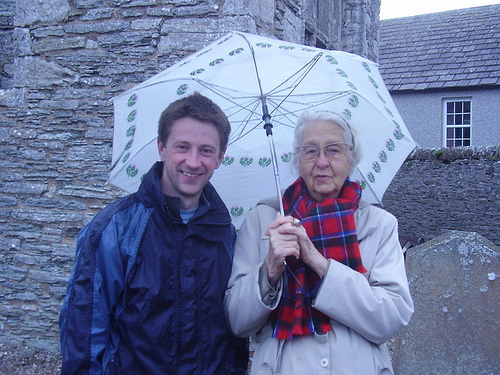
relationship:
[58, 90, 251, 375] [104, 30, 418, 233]
man under umbrella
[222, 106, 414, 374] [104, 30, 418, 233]
woman under umbrella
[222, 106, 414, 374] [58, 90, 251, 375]
woman next to man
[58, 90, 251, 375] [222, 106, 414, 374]
man next to woman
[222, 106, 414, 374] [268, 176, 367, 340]
woman has scarf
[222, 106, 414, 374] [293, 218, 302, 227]
woman has ring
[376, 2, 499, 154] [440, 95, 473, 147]
house has window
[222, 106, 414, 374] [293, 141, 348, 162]
woman has glasses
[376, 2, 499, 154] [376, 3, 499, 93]
house has roof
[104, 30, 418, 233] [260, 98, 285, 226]
umbrella has pole